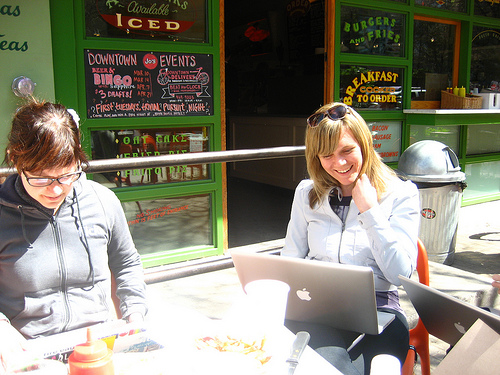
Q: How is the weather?
A: Very sunny.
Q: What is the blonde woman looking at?
A: Laptop.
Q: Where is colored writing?
A: On a chalkboard.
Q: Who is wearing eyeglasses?
A: Woman on left.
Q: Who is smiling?
A: Blonde woman.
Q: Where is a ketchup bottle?
A: On the table.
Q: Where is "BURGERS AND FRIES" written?
A: On a window.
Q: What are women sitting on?
A: Chairs.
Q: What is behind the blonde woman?
A: Trash can.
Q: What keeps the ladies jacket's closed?
A: Zippers.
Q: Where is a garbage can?
A: Behind woman on laptop.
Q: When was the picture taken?
A: While the sun was out.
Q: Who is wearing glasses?
A: Woman in dark grey hoodie.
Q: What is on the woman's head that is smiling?
A: Sunglasses.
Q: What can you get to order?
A: Breakfast.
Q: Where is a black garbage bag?
A: In trash can.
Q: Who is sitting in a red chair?
A: Blonde woman.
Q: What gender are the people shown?
A: Female.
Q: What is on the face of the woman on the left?
A: Glasses.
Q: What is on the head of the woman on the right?
A: Sunglasses.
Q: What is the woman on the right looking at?
A: Laptop.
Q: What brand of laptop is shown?
A: Apple.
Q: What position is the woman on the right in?
A: Sitting.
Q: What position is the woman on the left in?
A: Sitting.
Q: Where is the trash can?
A: Behind woman on the right.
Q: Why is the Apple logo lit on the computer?
A: The laptop is turned on.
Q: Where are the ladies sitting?
A: At a sidewalk table.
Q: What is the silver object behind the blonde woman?
A: A trash can.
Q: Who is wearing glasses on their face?
A: The brunette woman.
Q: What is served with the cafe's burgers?
A: Fries.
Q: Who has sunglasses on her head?
A: The blonde woman.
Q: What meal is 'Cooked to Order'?
A: Breakfast.